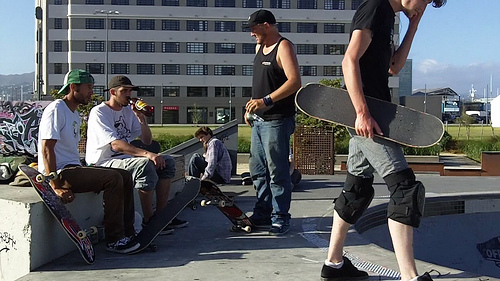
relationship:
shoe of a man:
[321, 256, 365, 279] [316, 2, 442, 279]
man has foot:
[316, 2, 442, 279] [318, 253, 375, 278]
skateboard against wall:
[17, 160, 102, 258] [3, 184, 48, 271]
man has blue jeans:
[227, 3, 309, 246] [239, 115, 305, 231]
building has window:
[23, 1, 443, 130] [128, 21, 161, 35]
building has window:
[23, 1, 443, 130] [108, 17, 135, 31]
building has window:
[23, 1, 443, 130] [49, 15, 69, 38]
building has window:
[23, 1, 443, 130] [294, 20, 324, 44]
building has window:
[23, 1, 443, 130] [182, 84, 212, 102]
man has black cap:
[240, 8, 305, 239] [240, 8, 277, 29]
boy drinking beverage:
[83, 74, 191, 236] [81, 75, 187, 239]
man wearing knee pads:
[316, 2, 442, 279] [382, 168, 426, 228]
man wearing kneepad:
[316, 2, 442, 279] [336, 166, 371, 223]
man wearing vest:
[240, 8, 305, 239] [251, 36, 297, 117]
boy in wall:
[39, 69, 141, 256] [0, 122, 244, 278]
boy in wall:
[92, 72, 192, 245] [0, 122, 244, 278]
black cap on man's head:
[237, 7, 281, 29] [235, 1, 288, 59]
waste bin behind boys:
[298, 123, 335, 179] [34, 0, 449, 279]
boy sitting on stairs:
[187, 124, 233, 182] [1, 145, 241, 278]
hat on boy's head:
[51, 67, 100, 94] [56, 59, 96, 112]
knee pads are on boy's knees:
[329, 169, 431, 231] [334, 166, 426, 226]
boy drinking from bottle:
[83, 74, 191, 236] [126, 94, 158, 124]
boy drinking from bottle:
[83, 74, 191, 236] [122, 96, 154, 118]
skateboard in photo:
[292, 81, 444, 148] [0, 0, 498, 280]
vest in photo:
[248, 36, 298, 116] [6, 5, 498, 279]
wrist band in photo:
[261, 88, 277, 107] [6, 5, 498, 279]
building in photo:
[31, 0, 402, 143] [6, 5, 498, 279]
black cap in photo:
[240, 8, 277, 29] [6, 5, 498, 279]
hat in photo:
[103, 75, 133, 92] [6, 5, 498, 279]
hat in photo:
[56, 68, 96, 95] [6, 5, 498, 279]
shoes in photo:
[311, 246, 362, 277] [6, 5, 498, 279]